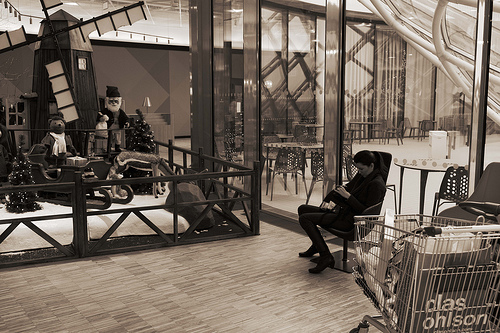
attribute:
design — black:
[170, 172, 286, 264]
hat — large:
[100, 63, 129, 118]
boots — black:
[297, 239, 331, 274]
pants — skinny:
[284, 205, 341, 264]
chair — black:
[369, 143, 399, 242]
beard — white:
[102, 88, 119, 114]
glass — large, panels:
[264, 1, 477, 162]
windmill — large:
[7, 6, 176, 148]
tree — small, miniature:
[7, 139, 51, 220]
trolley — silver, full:
[344, 198, 490, 325]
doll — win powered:
[45, 100, 73, 163]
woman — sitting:
[297, 166, 383, 260]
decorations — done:
[16, 9, 271, 250]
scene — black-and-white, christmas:
[9, 10, 479, 332]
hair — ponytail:
[354, 145, 392, 177]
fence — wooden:
[6, 133, 256, 277]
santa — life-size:
[91, 84, 137, 137]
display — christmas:
[6, 7, 258, 243]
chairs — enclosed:
[244, 122, 374, 202]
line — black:
[180, 247, 278, 280]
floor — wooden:
[27, 269, 297, 331]